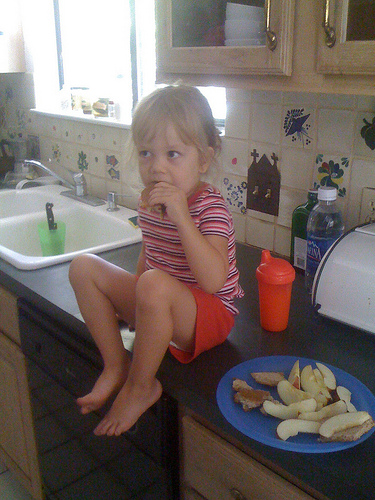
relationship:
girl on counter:
[54, 80, 240, 456] [2, 168, 375, 500]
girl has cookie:
[54, 80, 240, 456] [135, 183, 169, 208]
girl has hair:
[54, 80, 240, 456] [117, 79, 234, 170]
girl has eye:
[54, 80, 240, 456] [132, 145, 157, 163]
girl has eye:
[54, 80, 240, 456] [165, 148, 183, 162]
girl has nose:
[54, 80, 240, 456] [147, 157, 170, 178]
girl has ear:
[54, 80, 240, 456] [196, 138, 217, 177]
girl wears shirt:
[54, 80, 240, 456] [128, 180, 255, 315]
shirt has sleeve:
[128, 180, 255, 315] [197, 196, 234, 241]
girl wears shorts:
[54, 80, 240, 456] [127, 270, 239, 368]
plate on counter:
[210, 351, 374, 461] [2, 168, 375, 500]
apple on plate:
[267, 362, 368, 441] [210, 351, 374, 461]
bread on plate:
[231, 365, 284, 414] [210, 351, 374, 461]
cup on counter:
[244, 246, 302, 336] [2, 168, 375, 500]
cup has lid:
[244, 246, 302, 336] [254, 247, 299, 289]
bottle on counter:
[304, 180, 350, 310] [2, 168, 375, 500]